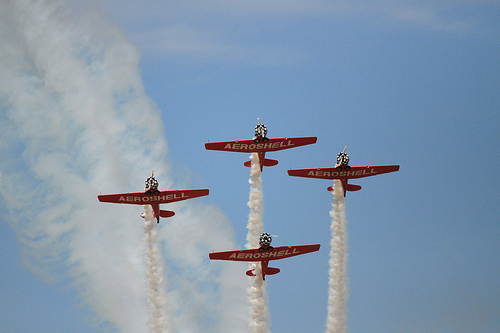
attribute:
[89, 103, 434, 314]
plains — four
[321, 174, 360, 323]
trail — smoke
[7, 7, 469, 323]
sky — blue, beautiful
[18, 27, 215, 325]
cloud — white, large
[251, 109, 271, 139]
propeller — spinning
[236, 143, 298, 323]
smoke — plane's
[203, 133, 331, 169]
wings — plane's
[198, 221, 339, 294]
airplane — red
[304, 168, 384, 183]
letters — white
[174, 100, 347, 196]
plane — leading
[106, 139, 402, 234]
planes — middle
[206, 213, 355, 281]
plane — back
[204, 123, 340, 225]
plane — lead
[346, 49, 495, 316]
sky — open